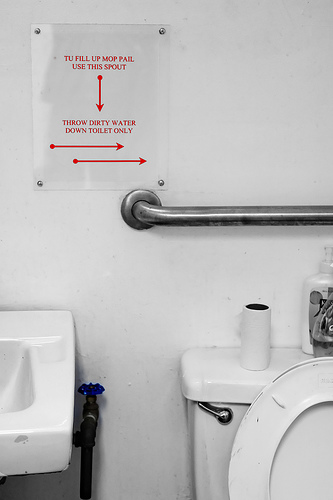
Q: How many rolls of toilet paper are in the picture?
A: 1.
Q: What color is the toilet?
A: White.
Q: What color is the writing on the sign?
A: Red.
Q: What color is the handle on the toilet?
A: Silver.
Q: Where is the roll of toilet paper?
A: On the toilet.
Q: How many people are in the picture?
A: Zero.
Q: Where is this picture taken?
A: A bathroom.